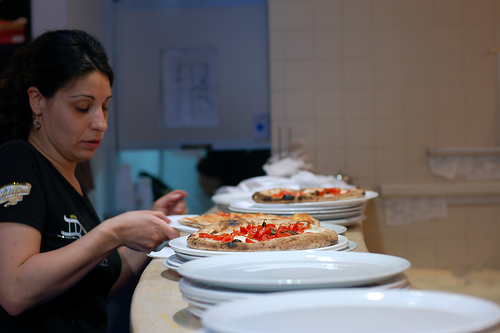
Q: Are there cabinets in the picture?
A: Yes, there is a cabinet.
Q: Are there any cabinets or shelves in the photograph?
A: Yes, there is a cabinet.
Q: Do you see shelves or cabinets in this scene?
A: Yes, there is a cabinet.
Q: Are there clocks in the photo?
A: No, there are no clocks.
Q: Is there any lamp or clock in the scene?
A: No, there are no clocks or lamps.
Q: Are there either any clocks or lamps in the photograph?
A: No, there are no clocks or lamps.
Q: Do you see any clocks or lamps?
A: No, there are no clocks or lamps.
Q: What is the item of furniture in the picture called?
A: The piece of furniture is a cabinet.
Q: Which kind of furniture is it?
A: The piece of furniture is a cabinet.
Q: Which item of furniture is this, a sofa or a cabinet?
A: That is a cabinet.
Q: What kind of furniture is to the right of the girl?
A: The piece of furniture is a cabinet.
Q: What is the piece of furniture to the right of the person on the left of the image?
A: The piece of furniture is a cabinet.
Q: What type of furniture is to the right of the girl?
A: The piece of furniture is a cabinet.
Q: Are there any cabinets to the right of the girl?
A: Yes, there is a cabinet to the right of the girl.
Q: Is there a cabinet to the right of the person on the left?
A: Yes, there is a cabinet to the right of the girl.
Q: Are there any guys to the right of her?
A: No, there is a cabinet to the right of the girl.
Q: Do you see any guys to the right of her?
A: No, there is a cabinet to the right of the girl.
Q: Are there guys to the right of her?
A: No, there is a cabinet to the right of the girl.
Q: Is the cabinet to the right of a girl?
A: Yes, the cabinet is to the right of a girl.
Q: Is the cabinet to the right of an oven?
A: No, the cabinet is to the right of a girl.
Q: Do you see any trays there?
A: No, there are no trays.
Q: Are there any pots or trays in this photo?
A: No, there are no trays or pots.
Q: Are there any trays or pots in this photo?
A: No, there are no trays or pots.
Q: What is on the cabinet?
A: The paper is on the cabinet.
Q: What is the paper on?
A: The paper is on the cabinet.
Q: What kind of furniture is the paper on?
A: The paper is on the cabinet.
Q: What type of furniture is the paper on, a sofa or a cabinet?
A: The paper is on a cabinet.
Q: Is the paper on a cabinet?
A: Yes, the paper is on a cabinet.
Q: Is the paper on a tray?
A: No, the paper is on a cabinet.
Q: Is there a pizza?
A: Yes, there is a pizza.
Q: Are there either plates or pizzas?
A: Yes, there is a pizza.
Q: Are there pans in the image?
A: No, there are no pans.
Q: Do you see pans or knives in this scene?
A: No, there are no pans or knives.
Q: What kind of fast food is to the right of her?
A: The food is a pizza.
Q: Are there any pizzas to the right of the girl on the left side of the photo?
A: Yes, there is a pizza to the right of the girl.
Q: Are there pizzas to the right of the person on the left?
A: Yes, there is a pizza to the right of the girl.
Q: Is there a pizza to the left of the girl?
A: No, the pizza is to the right of the girl.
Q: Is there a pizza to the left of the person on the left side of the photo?
A: No, the pizza is to the right of the girl.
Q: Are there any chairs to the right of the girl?
A: No, there is a pizza to the right of the girl.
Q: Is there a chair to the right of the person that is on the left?
A: No, there is a pizza to the right of the girl.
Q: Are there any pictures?
A: No, there are no pictures.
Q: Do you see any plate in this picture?
A: Yes, there is a plate.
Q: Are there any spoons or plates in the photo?
A: Yes, there is a plate.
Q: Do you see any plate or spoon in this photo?
A: Yes, there is a plate.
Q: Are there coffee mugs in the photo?
A: No, there are no coffee mugs.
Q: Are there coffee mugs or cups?
A: No, there are no coffee mugs or cups.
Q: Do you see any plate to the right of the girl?
A: Yes, there is a plate to the right of the girl.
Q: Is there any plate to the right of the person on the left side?
A: Yes, there is a plate to the right of the girl.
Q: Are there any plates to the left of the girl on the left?
A: No, the plate is to the right of the girl.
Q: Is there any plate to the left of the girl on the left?
A: No, the plate is to the right of the girl.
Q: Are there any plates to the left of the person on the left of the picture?
A: No, the plate is to the right of the girl.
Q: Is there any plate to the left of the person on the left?
A: No, the plate is to the right of the girl.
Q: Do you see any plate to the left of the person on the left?
A: No, the plate is to the right of the girl.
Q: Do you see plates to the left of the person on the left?
A: No, the plate is to the right of the girl.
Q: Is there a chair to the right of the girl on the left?
A: No, there is a plate to the right of the girl.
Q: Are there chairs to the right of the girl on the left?
A: No, there is a plate to the right of the girl.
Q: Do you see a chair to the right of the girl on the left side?
A: No, there is a plate to the right of the girl.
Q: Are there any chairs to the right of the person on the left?
A: No, there is a plate to the right of the girl.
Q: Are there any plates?
A: Yes, there is a plate.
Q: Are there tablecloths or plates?
A: Yes, there is a plate.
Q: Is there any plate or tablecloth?
A: Yes, there is a plate.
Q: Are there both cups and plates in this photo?
A: No, there is a plate but no cups.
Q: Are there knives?
A: No, there are no knives.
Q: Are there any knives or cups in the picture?
A: No, there are no knives or cups.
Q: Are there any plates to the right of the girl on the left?
A: Yes, there is a plate to the right of the girl.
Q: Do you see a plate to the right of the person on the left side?
A: Yes, there is a plate to the right of the girl.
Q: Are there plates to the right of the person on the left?
A: Yes, there is a plate to the right of the girl.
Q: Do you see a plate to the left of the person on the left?
A: No, the plate is to the right of the girl.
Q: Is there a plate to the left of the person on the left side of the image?
A: No, the plate is to the right of the girl.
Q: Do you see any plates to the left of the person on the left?
A: No, the plate is to the right of the girl.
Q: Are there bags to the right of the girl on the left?
A: No, there is a plate to the right of the girl.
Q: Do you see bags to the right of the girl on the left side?
A: No, there is a plate to the right of the girl.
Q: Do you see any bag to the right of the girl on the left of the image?
A: No, there is a plate to the right of the girl.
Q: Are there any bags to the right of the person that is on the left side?
A: No, there is a plate to the right of the girl.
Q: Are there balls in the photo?
A: No, there are no balls.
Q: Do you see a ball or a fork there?
A: No, there are no balls or forks.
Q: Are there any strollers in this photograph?
A: No, there are no strollers.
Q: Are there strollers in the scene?
A: No, there are no strollers.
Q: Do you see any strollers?
A: No, there are no strollers.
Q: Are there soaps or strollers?
A: No, there are no strollers or soaps.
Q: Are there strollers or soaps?
A: No, there are no strollers or soaps.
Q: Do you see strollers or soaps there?
A: No, there are no strollers or soaps.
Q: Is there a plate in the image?
A: Yes, there is a plate.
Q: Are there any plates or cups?
A: Yes, there is a plate.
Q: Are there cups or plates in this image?
A: Yes, there is a plate.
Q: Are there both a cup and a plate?
A: No, there is a plate but no cups.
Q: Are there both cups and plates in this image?
A: No, there is a plate but no cups.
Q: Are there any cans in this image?
A: No, there are no cans.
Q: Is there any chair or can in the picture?
A: No, there are no cans or chairs.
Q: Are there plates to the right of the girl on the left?
A: Yes, there is a plate to the right of the girl.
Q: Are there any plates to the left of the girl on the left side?
A: No, the plate is to the right of the girl.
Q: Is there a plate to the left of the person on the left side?
A: No, the plate is to the right of the girl.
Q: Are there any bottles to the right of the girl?
A: No, there is a plate to the right of the girl.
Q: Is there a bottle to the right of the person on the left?
A: No, there is a plate to the right of the girl.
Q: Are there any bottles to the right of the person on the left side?
A: No, there is a plate to the right of the girl.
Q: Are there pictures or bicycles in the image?
A: No, there are no pictures or bicycles.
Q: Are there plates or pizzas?
A: Yes, there is a plate.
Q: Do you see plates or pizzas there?
A: Yes, there is a plate.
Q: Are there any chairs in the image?
A: No, there are no chairs.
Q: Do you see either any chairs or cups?
A: No, there are no chairs or cups.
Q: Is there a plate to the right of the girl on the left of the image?
A: Yes, there is a plate to the right of the girl.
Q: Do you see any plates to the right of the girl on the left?
A: Yes, there is a plate to the right of the girl.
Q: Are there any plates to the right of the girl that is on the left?
A: Yes, there is a plate to the right of the girl.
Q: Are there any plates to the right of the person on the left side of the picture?
A: Yes, there is a plate to the right of the girl.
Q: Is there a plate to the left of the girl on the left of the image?
A: No, the plate is to the right of the girl.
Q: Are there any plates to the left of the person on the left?
A: No, the plate is to the right of the girl.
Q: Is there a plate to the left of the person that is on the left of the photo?
A: No, the plate is to the right of the girl.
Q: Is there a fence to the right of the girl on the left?
A: No, there is a plate to the right of the girl.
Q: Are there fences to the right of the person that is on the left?
A: No, there is a plate to the right of the girl.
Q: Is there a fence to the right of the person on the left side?
A: No, there is a plate to the right of the girl.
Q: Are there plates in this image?
A: Yes, there is a plate.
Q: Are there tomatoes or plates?
A: Yes, there is a plate.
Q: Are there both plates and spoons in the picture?
A: No, there is a plate but no spoons.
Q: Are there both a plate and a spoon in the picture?
A: No, there is a plate but no spoons.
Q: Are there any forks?
A: No, there are no forks.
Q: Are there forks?
A: No, there are no forks.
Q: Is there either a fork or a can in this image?
A: No, there are no forks or cans.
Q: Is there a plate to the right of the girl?
A: Yes, there is a plate to the right of the girl.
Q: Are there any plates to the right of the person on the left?
A: Yes, there is a plate to the right of the girl.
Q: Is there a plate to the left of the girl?
A: No, the plate is to the right of the girl.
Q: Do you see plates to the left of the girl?
A: No, the plate is to the right of the girl.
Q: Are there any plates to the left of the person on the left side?
A: No, the plate is to the right of the girl.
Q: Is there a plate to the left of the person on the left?
A: No, the plate is to the right of the girl.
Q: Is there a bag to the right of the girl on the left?
A: No, there is a plate to the right of the girl.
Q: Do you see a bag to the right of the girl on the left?
A: No, there is a plate to the right of the girl.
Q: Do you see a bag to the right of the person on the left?
A: No, there is a plate to the right of the girl.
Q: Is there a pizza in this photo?
A: Yes, there is a pizza.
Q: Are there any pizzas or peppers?
A: Yes, there is a pizza.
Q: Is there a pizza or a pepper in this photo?
A: Yes, there is a pizza.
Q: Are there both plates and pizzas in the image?
A: Yes, there are both a pizza and a plate.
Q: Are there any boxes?
A: No, there are no boxes.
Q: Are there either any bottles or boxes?
A: No, there are no boxes or bottles.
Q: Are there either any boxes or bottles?
A: No, there are no boxes or bottles.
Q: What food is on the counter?
A: The food is a pizza.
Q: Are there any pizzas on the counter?
A: Yes, there is a pizza on the counter.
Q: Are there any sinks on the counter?
A: No, there is a pizza on the counter.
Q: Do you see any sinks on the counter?
A: No, there is a pizza on the counter.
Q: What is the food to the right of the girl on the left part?
A: The food is a pizza.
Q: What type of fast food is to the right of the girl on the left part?
A: The food is a pizza.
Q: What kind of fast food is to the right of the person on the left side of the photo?
A: The food is a pizza.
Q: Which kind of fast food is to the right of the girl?
A: The food is a pizza.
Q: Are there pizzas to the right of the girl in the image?
A: Yes, there is a pizza to the right of the girl.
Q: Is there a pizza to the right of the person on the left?
A: Yes, there is a pizza to the right of the girl.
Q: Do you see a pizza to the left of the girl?
A: No, the pizza is to the right of the girl.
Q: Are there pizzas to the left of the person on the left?
A: No, the pizza is to the right of the girl.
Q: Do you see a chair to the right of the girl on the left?
A: No, there is a pizza to the right of the girl.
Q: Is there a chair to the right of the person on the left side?
A: No, there is a pizza to the right of the girl.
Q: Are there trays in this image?
A: No, there are no trays.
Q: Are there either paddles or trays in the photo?
A: No, there are no trays or paddles.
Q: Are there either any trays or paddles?
A: No, there are no trays or paddles.